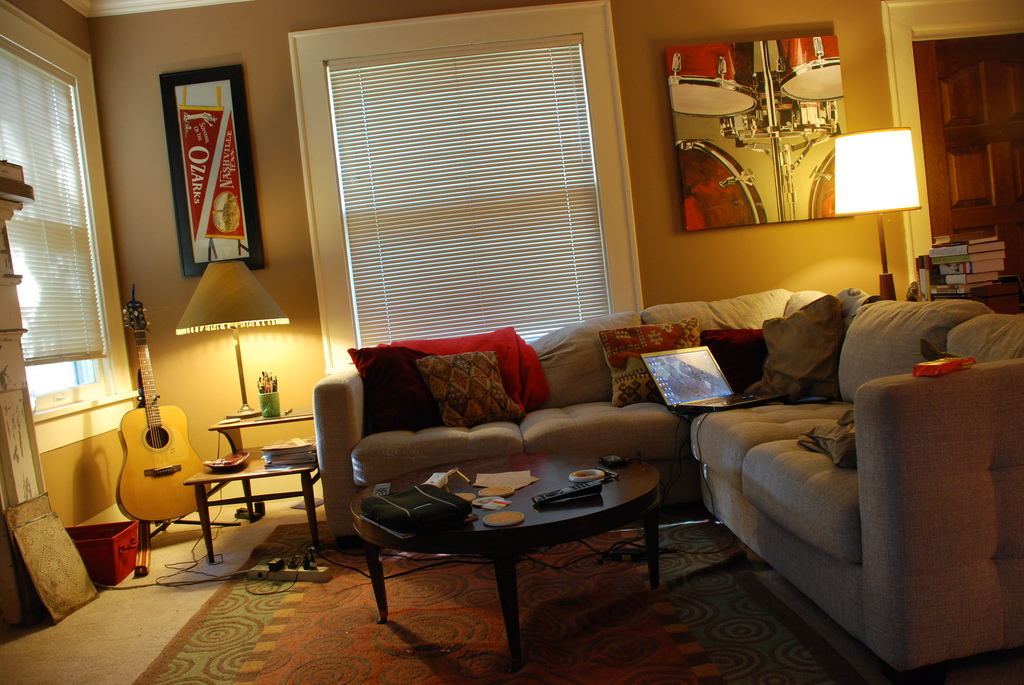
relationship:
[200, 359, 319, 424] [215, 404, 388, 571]
mug on table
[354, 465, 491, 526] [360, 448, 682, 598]
album on table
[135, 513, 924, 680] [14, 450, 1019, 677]
rug on floor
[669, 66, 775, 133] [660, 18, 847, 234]
drum on painting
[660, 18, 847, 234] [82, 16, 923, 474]
painting on wall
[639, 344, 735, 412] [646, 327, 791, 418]
screen on laptop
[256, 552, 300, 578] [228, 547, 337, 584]
plugs in strip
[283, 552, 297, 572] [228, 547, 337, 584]
plugs in strip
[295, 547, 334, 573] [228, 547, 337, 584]
plugs in strip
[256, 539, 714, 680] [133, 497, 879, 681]
pattern on rug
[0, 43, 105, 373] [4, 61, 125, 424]
miniblinds almost completely down on window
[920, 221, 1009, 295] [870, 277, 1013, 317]
books on table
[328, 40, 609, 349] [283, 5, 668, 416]
blinds on window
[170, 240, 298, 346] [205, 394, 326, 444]
lamp on table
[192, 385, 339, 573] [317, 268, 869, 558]
table next to couch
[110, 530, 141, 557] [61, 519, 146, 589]
handle on container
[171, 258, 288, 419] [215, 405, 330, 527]
lamp on table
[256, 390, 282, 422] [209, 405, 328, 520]
mug on table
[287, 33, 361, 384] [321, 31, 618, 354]
border of window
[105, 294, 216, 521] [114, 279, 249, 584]
guitar on stand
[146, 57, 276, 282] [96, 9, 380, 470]
picture on wall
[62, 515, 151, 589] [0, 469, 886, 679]
container on floor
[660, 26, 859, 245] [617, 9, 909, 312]
painting on wall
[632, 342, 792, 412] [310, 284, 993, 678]
laptop on couch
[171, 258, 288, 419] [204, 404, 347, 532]
lamp on table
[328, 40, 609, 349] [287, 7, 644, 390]
blinds on window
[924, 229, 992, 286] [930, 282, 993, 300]
books on table